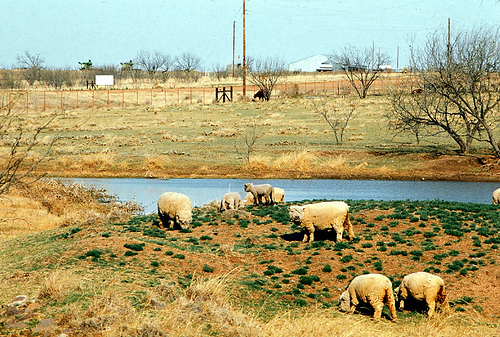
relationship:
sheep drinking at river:
[244, 176, 273, 199] [301, 181, 348, 196]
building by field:
[289, 58, 316, 73] [305, 83, 331, 91]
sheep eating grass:
[160, 192, 192, 233] [169, 232, 205, 240]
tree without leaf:
[312, 100, 356, 145] [349, 144, 360, 150]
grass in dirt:
[169, 232, 205, 240] [194, 228, 221, 240]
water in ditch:
[308, 181, 329, 193] [108, 197, 133, 205]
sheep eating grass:
[337, 272, 393, 313] [317, 299, 331, 308]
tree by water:
[312, 100, 356, 145] [308, 181, 329, 193]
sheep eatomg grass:
[337, 272, 393, 313] [317, 299, 331, 308]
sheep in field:
[244, 176, 273, 199] [305, 83, 331, 91]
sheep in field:
[160, 192, 192, 233] [305, 83, 331, 91]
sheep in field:
[337, 272, 393, 313] [305, 83, 331, 91]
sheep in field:
[395, 267, 450, 314] [305, 83, 331, 91]